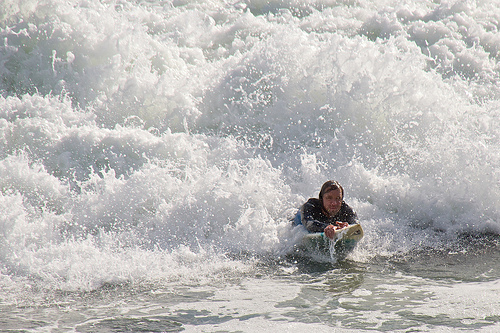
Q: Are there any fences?
A: No, there are no fences.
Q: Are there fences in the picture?
A: No, there are no fences.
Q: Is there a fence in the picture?
A: No, there are no fences.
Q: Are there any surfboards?
A: Yes, there is a surfboard.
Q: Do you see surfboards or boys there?
A: Yes, there is a surfboard.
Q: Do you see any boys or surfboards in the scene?
A: Yes, there is a surfboard.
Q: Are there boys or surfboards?
A: Yes, there is a surfboard.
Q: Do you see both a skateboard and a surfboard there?
A: No, there is a surfboard but no skateboards.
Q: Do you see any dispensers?
A: No, there are no dispensers.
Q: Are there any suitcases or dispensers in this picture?
A: No, there are no dispensers or suitcases.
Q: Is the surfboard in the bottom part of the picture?
A: Yes, the surfboard is in the bottom of the image.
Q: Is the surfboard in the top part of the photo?
A: No, the surfboard is in the bottom of the image.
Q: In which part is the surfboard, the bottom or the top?
A: The surfboard is in the bottom of the image.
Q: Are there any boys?
A: No, there are no boys.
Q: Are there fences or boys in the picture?
A: No, there are no boys or fences.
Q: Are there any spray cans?
A: No, there are no spray cans.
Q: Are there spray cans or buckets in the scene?
A: No, there are no spray cans or buckets.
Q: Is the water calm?
A: Yes, the water is calm.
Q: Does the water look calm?
A: Yes, the water is calm.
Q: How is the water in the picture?
A: The water is calm.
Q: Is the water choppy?
A: No, the water is calm.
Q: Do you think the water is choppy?
A: No, the water is calm.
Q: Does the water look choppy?
A: No, the water is calm.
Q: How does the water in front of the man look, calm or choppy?
A: The water is calm.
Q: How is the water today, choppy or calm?
A: The water is calm.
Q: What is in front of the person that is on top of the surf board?
A: The water is in front of the man.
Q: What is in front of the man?
A: The water is in front of the man.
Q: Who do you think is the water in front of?
A: The water is in front of the man.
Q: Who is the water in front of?
A: The water is in front of the man.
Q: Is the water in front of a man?
A: Yes, the water is in front of a man.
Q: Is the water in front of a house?
A: No, the water is in front of a man.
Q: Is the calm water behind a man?
A: No, the water is in front of a man.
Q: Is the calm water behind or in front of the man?
A: The water is in front of the man.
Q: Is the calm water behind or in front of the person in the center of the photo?
A: The water is in front of the man.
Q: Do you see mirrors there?
A: No, there are no mirrors.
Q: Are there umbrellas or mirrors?
A: No, there are no mirrors or umbrellas.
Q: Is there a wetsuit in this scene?
A: Yes, there is a wetsuit.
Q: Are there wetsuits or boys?
A: Yes, there is a wetsuit.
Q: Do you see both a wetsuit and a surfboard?
A: Yes, there are both a wetsuit and a surfboard.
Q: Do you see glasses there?
A: No, there are no glasses.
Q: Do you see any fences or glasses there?
A: No, there are no glasses or fences.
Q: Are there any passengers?
A: No, there are no passengers.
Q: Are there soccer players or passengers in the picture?
A: No, there are no passengers or soccer players.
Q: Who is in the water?
A: The man is in the water.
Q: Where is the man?
A: The man is in the water.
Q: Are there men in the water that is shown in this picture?
A: Yes, there is a man in the water.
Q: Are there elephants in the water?
A: No, there is a man in the water.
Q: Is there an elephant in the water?
A: No, there is a man in the water.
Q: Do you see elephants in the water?
A: No, there is a man in the water.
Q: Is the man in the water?
A: Yes, the man is in the water.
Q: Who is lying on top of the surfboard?
A: The man is lying on top of the surfboard.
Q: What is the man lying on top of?
A: The man is lying on top of the surfboard.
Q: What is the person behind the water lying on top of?
A: The man is lying on top of the surfboard.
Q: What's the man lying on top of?
A: The man is lying on top of the surfboard.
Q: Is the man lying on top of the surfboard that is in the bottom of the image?
A: Yes, the man is lying on top of the surfboard.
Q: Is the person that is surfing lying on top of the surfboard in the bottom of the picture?
A: Yes, the man is lying on top of the surfboard.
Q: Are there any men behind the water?
A: Yes, there is a man behind the water.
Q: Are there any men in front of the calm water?
A: No, the man is behind the water.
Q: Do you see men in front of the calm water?
A: No, the man is behind the water.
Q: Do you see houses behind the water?
A: No, there is a man behind the water.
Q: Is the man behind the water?
A: Yes, the man is behind the water.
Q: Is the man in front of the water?
A: No, the man is behind the water.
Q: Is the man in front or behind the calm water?
A: The man is behind the water.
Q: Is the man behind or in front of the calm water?
A: The man is behind the water.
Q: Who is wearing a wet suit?
A: The man is wearing a wet suit.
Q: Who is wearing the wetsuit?
A: The man is wearing a wet suit.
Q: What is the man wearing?
A: The man is wearing a wetsuit.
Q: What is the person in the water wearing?
A: The man is wearing a wetsuit.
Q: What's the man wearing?
A: The man is wearing a wetsuit.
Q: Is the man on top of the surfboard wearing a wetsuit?
A: Yes, the man is wearing a wetsuit.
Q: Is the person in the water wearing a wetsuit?
A: Yes, the man is wearing a wetsuit.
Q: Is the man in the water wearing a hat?
A: No, the man is wearing a wetsuit.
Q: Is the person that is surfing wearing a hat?
A: No, the man is wearing a wetsuit.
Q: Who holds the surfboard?
A: The man holds the surfboard.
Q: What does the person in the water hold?
A: The man holds the surfboard.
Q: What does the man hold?
A: The man holds the surfboard.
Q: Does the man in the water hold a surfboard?
A: Yes, the man holds a surfboard.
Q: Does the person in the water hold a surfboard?
A: Yes, the man holds a surfboard.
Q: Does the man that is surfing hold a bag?
A: No, the man holds a surfboard.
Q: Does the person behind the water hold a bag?
A: No, the man holds a surfboard.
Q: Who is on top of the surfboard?
A: The man is on top of the surfboard.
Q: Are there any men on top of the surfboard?
A: Yes, there is a man on top of the surfboard.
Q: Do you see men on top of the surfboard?
A: Yes, there is a man on top of the surfboard.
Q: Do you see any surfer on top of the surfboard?
A: No, there is a man on top of the surfboard.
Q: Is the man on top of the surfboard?
A: Yes, the man is on top of the surfboard.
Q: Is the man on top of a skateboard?
A: No, the man is on top of the surfboard.